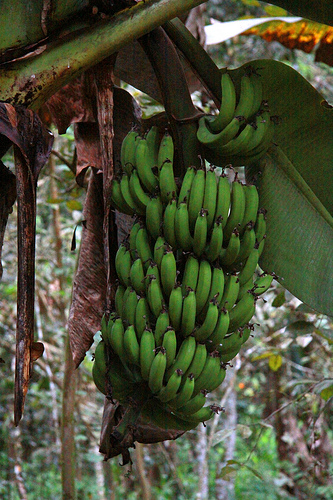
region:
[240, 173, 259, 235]
The banana is green.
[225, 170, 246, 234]
The banana is green.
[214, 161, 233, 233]
The banana is green.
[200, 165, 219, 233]
The banana is green.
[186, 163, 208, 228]
The banana is green.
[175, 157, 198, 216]
The banana is green.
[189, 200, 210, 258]
The banana is green.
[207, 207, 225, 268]
The banana is green.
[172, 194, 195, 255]
The banana is green.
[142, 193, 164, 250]
The banana is green.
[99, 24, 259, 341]
banana hanging from its tree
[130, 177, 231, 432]
the bananas are small in size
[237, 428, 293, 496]
the plants are seen through th branches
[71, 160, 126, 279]
the leaf is dried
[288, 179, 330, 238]
flower leaf is green in color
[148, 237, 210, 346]
bananas are green in color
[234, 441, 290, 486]
plants are greeb in color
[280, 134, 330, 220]
Green color banana leaves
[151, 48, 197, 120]
Stem of the banana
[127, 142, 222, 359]
Green color bunch of banana's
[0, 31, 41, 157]
Apparent trunk of the banana tree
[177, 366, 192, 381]
The nasty bit of the banana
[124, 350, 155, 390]
The best bit of the banana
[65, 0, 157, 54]
False stem or trunk of the tree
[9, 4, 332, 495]
Banana tree in the forest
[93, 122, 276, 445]
A long large bunch of green bananas.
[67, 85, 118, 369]
Dead brown leaf going down the left side of the bananas.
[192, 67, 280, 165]
Smaller bunch of green bananas to the upper right.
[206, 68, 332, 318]
Very large gree right side leaf.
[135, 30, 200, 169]
Thick green banana plant stem.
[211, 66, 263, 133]
The top three most green bananas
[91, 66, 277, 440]
Long large bunch of green bananas.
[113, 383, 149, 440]
Green stem hanging at the bottom of the bananas.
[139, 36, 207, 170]
Thick dark green stem going to the bunch of bananas.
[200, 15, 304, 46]
A white illuminated side of a folded leaf.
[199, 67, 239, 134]
The banana is green.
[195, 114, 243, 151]
The banana is green.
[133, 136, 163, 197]
The banana is green.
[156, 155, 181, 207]
The banana is green.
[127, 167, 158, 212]
The banana is green.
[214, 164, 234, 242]
The banana is green.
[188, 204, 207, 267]
The banana is green.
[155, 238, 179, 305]
The banana is green.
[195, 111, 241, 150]
banana is color green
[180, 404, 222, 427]
banana is color green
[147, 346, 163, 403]
banana is color green